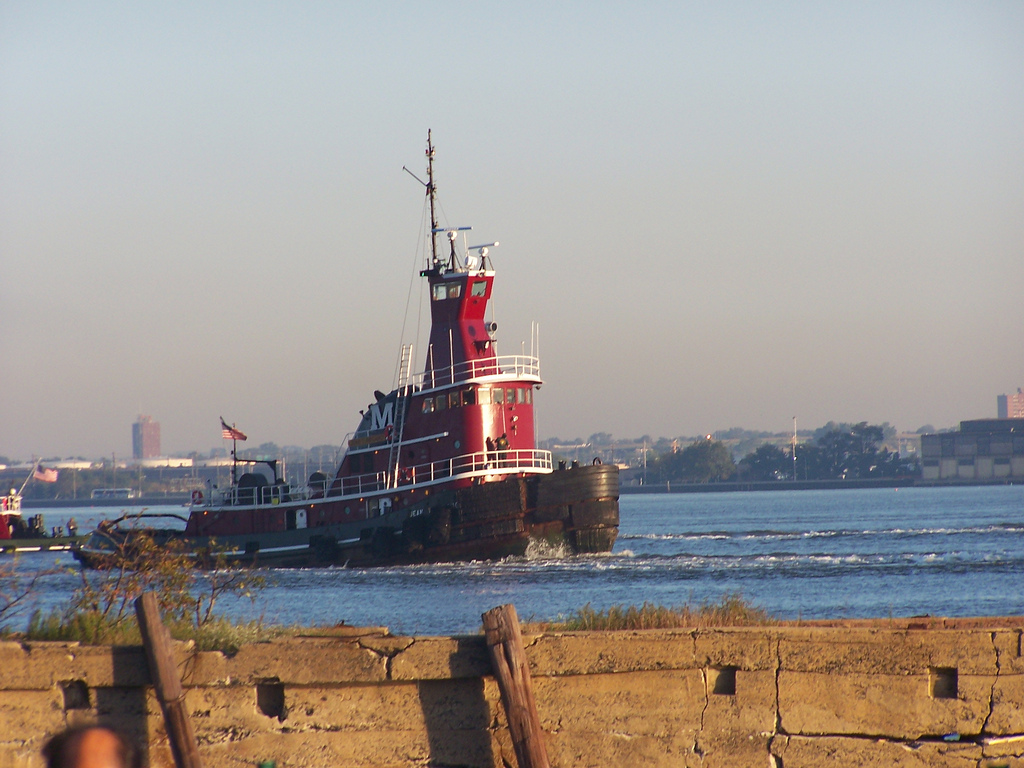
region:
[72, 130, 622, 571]
a large red boat with a black bottom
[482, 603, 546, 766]
a wooden post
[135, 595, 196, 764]
a wooden post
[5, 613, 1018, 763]
a rock wall with large cracks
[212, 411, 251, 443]
a red, white, and blue American flag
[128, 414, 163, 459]
a tall red brick building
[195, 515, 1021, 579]
ripples in the water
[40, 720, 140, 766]
a blurred spot on the image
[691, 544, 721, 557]
wave on the water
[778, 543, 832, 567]
wave on the water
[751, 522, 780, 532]
wave on the water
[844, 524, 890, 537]
wave on the water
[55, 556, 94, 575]
wave on the water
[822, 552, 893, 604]
wave on the water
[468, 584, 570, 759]
Old brown wooden pillar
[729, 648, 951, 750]
Old decaying stone wall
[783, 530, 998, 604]
Beautiful clear blue water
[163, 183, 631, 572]
An enormous red colored boat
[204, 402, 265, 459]
A red white and blue American flag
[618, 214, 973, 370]
Clear grey cloudless sky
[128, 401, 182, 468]
Tall grey storied building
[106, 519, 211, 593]
A withered brown shrub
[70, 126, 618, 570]
Red rescue boat with the letter M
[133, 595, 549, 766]
Two wooden sticks laying on the wall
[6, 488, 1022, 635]
Blue bay with waves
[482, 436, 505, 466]
Two men on a boat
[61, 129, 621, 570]
American flag on side of boat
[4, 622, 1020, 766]
Rocky wall with cracks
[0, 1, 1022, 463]
Afternoon overcast sky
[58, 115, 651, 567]
boat in body of water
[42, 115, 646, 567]
boat in water is red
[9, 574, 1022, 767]
wall in front of water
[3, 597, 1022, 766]
wall by water is concrete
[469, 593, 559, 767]
pole leaning against wall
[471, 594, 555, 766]
pole against wall is wood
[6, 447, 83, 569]
small boat in rear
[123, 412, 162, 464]
tall building in distance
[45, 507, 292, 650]
bare bush on wall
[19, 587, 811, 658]
grass on top of wall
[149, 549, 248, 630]
green leaves on the tree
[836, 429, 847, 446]
green leaves on the tree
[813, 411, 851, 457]
green leaves on the tree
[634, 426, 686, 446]
green leaves on the tree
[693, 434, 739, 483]
green leaves on the tree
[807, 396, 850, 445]
green leaves on the tree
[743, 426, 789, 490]
green leaves on the tree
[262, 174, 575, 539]
A large red boat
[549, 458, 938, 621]
A large body of water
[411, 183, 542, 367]
A tall tower on the boat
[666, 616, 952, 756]
A brick wall separating the water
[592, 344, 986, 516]
Buildings in the background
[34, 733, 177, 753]
A man with no hair